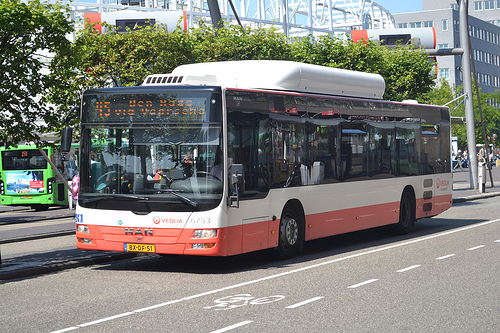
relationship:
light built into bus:
[190, 227, 219, 241] [56, 58, 454, 260]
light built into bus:
[74, 221, 90, 233] [56, 58, 454, 260]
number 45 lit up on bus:
[93, 99, 112, 119] [56, 58, 454, 260]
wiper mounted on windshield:
[77, 190, 148, 200] [80, 123, 222, 211]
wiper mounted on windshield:
[129, 186, 198, 207] [80, 123, 222, 211]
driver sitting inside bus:
[211, 157, 233, 183] [56, 58, 454, 260]